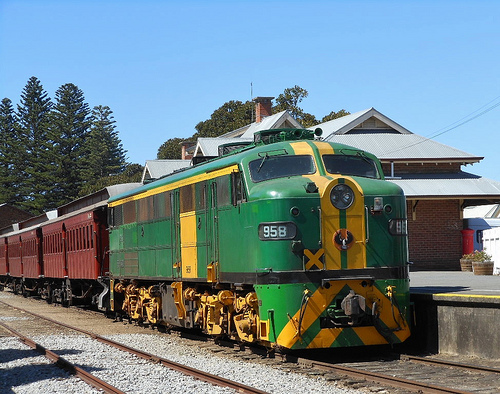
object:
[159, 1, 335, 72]
sky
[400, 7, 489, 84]
blue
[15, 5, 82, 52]
cloudless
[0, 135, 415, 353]
train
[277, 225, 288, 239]
numbers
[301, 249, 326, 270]
x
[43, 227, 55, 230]
red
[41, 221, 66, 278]
cars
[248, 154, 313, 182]
windows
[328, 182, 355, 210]
light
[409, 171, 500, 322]
station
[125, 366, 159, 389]
gravel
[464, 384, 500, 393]
tracks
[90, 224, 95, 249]
windows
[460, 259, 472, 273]
pots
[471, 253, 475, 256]
flowers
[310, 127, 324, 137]
horns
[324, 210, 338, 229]
yellow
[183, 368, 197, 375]
metal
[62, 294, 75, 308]
wheels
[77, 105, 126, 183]
trees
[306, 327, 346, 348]
stripes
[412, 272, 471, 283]
concrete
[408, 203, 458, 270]
building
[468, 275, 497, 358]
platform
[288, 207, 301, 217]
headlight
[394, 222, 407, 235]
number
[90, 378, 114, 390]
steel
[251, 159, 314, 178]
windshield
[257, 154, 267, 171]
wiper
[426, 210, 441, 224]
red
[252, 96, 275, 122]
chimney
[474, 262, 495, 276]
pot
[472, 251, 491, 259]
plant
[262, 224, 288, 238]
958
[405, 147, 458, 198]
roof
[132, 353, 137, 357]
stones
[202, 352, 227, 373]
ground